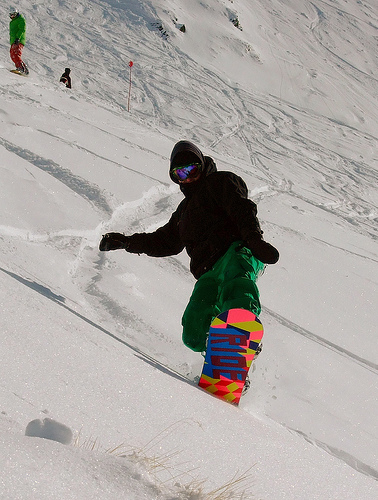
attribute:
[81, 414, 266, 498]
grass — yellow , tan, glistening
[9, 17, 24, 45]
coat — snow, green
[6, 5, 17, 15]
helmet — white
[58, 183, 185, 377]
trail — curved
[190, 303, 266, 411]
board — multicolored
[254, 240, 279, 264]
mitten — black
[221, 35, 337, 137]
snow boarder — wearing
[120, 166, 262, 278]
jacket — black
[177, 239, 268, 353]
pants — green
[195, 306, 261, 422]
snow board — multicolored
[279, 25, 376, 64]
no subject — blue 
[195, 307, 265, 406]
board — colorful, mosaic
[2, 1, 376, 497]
snow — untouched, littered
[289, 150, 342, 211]
clouds — white 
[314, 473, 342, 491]
sky — blue 